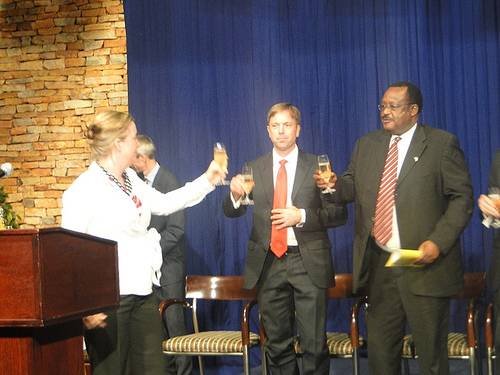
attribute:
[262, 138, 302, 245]
tie — plain , red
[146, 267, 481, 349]
chairs — wooden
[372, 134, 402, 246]
tie — red, white, striped